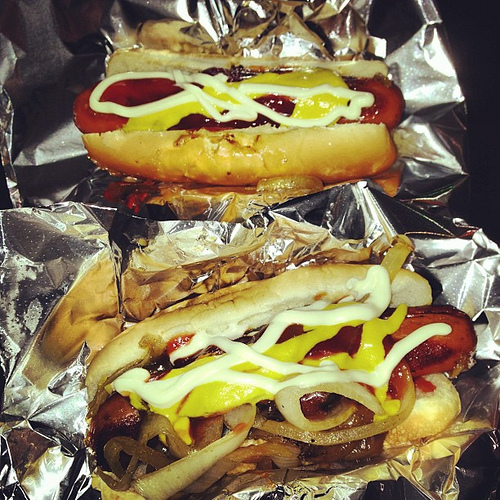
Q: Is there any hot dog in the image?
A: Yes, there is a hot dog.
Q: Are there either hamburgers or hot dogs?
A: Yes, there is a hot dog.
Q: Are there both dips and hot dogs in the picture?
A: No, there is a hot dog but no dips.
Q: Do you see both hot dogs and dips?
A: No, there is a hot dog but no dips.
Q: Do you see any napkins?
A: No, there are no napkins.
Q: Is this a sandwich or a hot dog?
A: This is a hot dog.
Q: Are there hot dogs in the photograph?
A: Yes, there is a hot dog.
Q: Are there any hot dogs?
A: Yes, there is a hot dog.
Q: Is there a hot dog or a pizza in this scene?
A: Yes, there is a hot dog.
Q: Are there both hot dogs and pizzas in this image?
A: No, there is a hot dog but no pizzas.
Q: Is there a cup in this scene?
A: No, there are no cups.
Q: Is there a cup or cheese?
A: No, there are no cups or cheese.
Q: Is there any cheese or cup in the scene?
A: No, there are no cups or cheese.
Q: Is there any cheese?
A: No, there is no cheese.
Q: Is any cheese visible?
A: No, there is no cheese.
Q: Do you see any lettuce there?
A: No, there is no lettuce.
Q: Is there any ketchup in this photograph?
A: Yes, there is ketchup.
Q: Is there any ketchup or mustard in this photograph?
A: Yes, there is ketchup.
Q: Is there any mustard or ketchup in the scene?
A: Yes, there is ketchup.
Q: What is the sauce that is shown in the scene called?
A: The sauce is ketchup.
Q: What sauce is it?
A: The sauce is ketchup.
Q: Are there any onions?
A: Yes, there is an onion.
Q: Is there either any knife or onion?
A: Yes, there is an onion.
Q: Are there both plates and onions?
A: No, there is an onion but no plates.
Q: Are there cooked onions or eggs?
A: Yes, there is a cooked onion.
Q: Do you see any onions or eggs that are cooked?
A: Yes, the onion is cooked.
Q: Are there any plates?
A: No, there are no plates.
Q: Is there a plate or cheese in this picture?
A: No, there are no plates or cheese.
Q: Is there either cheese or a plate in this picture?
A: No, there are no plates or cheese.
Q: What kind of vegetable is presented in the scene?
A: The vegetable is an onion.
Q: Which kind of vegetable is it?
A: The vegetable is an onion.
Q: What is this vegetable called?
A: This is an onion.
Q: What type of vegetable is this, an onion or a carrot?
A: This is an onion.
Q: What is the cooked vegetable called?
A: The vegetable is an onion.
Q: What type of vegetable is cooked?
A: The vegetable is an onion.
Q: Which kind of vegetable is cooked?
A: The vegetable is an onion.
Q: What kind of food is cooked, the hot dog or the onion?
A: The onion is cooked.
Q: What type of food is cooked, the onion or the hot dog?
A: The onion is cooked.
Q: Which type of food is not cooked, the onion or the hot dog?
A: The hot dog is not cooked.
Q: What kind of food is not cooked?
A: The food is a hot dog.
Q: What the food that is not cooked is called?
A: The food is a hot dog.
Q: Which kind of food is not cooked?
A: The food is a hot dog.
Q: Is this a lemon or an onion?
A: This is an onion.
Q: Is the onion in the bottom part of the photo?
A: Yes, the onion is in the bottom of the image.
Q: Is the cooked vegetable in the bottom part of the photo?
A: Yes, the onion is in the bottom of the image.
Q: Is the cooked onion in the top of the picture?
A: No, the onion is in the bottom of the image.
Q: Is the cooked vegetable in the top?
A: No, the onion is in the bottom of the image.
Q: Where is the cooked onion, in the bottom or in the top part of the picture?
A: The onion is in the bottom of the image.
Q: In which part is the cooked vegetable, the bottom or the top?
A: The onion is in the bottom of the image.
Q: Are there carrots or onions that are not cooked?
A: No, there is an onion but it is cooked.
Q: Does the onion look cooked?
A: Yes, the onion is cooked.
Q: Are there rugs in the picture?
A: No, there are no rugs.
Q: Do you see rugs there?
A: No, there are no rugs.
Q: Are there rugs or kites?
A: No, there are no rugs or kites.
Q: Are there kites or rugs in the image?
A: No, there are no rugs or kites.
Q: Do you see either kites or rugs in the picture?
A: No, there are no rugs or kites.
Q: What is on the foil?
A: The bun is on the foil.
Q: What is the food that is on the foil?
A: The food is a bun.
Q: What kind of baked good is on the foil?
A: The food is a bun.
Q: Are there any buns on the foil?
A: Yes, there is a bun on the foil.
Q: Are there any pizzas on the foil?
A: No, there is a bun on the foil.